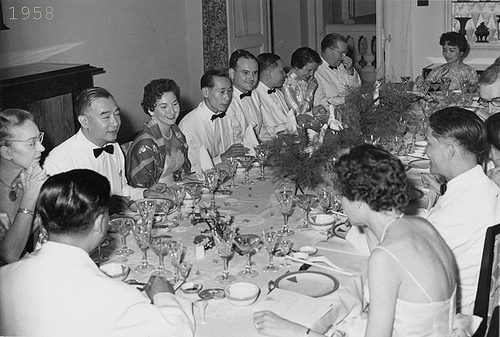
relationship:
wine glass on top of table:
[273, 185, 297, 238] [39, 80, 499, 316]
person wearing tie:
[39, 86, 147, 208] [89, 143, 119, 164]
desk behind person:
[0, 54, 112, 147] [39, 86, 147, 208]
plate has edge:
[272, 271, 341, 301] [331, 281, 343, 297]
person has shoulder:
[39, 86, 147, 208] [41, 127, 85, 178]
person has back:
[326, 141, 481, 337] [379, 208, 463, 308]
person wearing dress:
[326, 141, 481, 337] [365, 243, 484, 337]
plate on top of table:
[272, 271, 341, 301] [39, 80, 499, 316]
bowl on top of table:
[308, 211, 336, 232] [39, 80, 499, 316]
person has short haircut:
[39, 86, 147, 208] [72, 84, 115, 117]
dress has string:
[365, 243, 484, 337] [370, 242, 433, 307]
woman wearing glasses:
[0, 106, 52, 264] [1, 129, 50, 151]